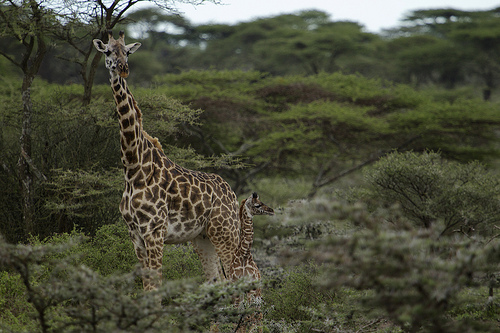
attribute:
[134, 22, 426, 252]
trees — green 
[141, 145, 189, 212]
pattern — brown , yellow 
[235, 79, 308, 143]
trees — green 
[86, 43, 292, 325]
giraffe — tall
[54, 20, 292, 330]
giraffe — tall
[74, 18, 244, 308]
giraffe — tall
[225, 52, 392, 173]
leaves — Brown 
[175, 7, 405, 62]
sky — blue 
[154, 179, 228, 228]
spots — brown , yellow 